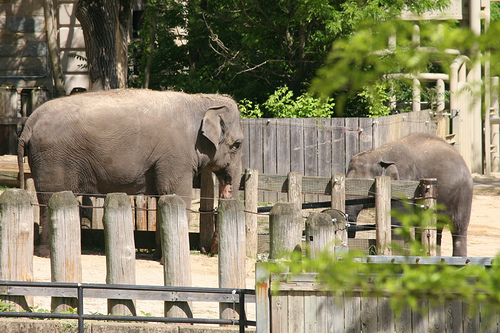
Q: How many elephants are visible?
A: Two.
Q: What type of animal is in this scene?
A: Elephant.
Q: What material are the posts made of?
A: Wood.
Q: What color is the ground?
A: Tan.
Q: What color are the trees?
A: Green.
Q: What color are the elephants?
A: Gray.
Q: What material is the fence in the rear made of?
A: Wood.